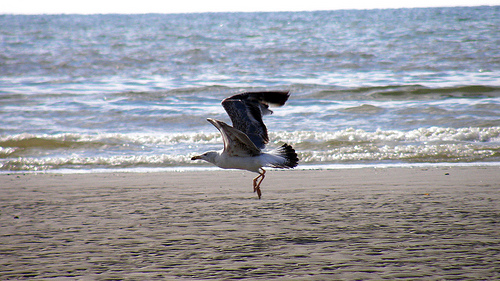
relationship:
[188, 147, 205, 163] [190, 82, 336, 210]
peck of a bird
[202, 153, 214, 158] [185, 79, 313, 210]
eye of a bird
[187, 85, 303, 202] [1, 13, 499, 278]
bird near a beach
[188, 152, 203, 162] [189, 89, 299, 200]
beak of a bird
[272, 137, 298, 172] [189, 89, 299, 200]
tail of a bird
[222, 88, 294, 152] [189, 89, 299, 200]
wing of a bird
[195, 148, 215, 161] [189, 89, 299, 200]
head of a bird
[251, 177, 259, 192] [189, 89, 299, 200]
foot of a bird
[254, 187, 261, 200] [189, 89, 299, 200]
foot of a bird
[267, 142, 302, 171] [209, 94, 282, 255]
tail following bird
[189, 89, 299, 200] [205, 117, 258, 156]
bird flying wing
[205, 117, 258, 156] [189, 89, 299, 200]
wing flying bird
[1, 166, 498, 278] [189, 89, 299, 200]
beach lying bird